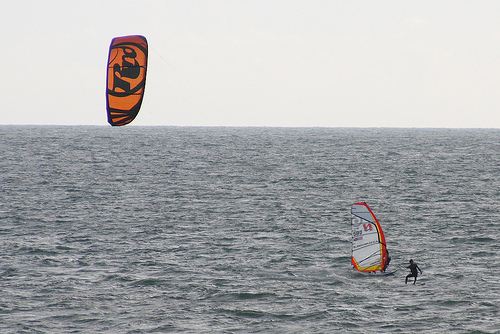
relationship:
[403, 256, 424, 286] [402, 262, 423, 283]
person wearing wetsuit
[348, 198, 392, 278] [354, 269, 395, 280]
sail connected to board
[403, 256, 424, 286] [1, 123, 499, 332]
person standing in water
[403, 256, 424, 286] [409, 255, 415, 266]
person has a head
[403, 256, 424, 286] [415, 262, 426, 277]
person has an arm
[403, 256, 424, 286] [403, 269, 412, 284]
person has a leg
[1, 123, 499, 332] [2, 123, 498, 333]
water has some ripples